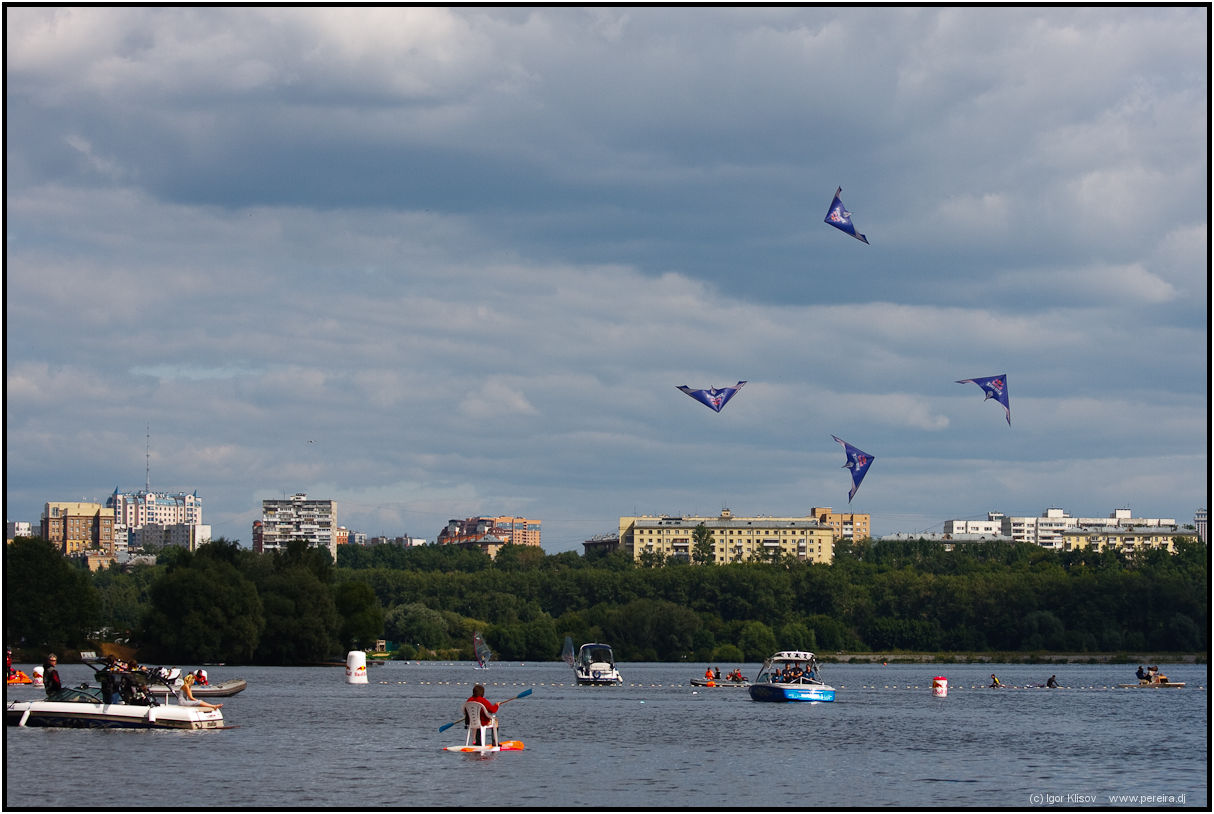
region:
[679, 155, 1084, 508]
large kites in sky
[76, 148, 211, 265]
white clouds in blue sky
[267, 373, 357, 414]
white clouds in blue sky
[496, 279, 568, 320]
white clouds in blue sky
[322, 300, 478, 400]
white clouds in blue sky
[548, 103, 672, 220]
white clouds in blue sky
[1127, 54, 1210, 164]
white clouds in blue sky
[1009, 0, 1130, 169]
white clouds in blue sky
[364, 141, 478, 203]
white clouds in blue sky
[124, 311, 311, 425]
white clouds in blue sky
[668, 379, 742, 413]
a purple kite in sky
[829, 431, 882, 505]
a purple kite in sky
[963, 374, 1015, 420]
a purple kite in sky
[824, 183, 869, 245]
a purple kite in sky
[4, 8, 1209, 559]
an overcast cloudy sky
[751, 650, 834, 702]
a blue motorboat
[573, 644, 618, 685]
a white and black motorboat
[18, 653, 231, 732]
a black and white boat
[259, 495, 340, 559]
a tall building in distance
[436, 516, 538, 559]
a tall building in distance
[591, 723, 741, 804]
the water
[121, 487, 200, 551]
a white building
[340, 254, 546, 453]
the clouds in the sky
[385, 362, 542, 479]
clouds are white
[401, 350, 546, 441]
white clouds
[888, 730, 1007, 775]
the water is blue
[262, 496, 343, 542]
a tall building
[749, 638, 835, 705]
blue boat on the water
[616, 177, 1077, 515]
four kites in the sky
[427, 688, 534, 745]
person holding blue oar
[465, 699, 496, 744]
white plastic chair person is sitting in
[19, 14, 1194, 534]
cloud covered sky above the water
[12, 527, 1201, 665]
green trees along the water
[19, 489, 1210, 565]
cityscape behind the trees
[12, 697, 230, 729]
white boat on the water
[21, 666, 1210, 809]
water the blue boat is on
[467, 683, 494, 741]
person wearing red shirt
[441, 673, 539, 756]
a man in a chair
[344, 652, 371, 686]
a large white buoy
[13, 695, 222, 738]
a long white raft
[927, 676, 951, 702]
a small orange and white buoy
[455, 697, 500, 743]
a white plastic chair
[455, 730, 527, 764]
an orange inflatable raft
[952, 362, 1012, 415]
a blue triangle shaped kite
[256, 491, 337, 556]
a grey multi storied building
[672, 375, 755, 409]
a kite in the sky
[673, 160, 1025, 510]
flags flying in the sky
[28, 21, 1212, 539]
blue sky with white clouds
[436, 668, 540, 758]
orange paddle boat with a man sitting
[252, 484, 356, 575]
white apartment building in the background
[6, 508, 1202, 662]
green bushes near blue water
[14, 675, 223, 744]
white barge floating in blue water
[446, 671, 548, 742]
man in orange sitting on chair holding paddle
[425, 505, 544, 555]
brown building in distance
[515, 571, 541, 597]
green leaves on the tree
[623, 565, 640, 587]
green leaves on the tree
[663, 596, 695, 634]
green leaves on the tree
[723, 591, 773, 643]
green leaves on the tree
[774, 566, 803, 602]
green leaves on the tree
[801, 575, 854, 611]
green leaves on the tree